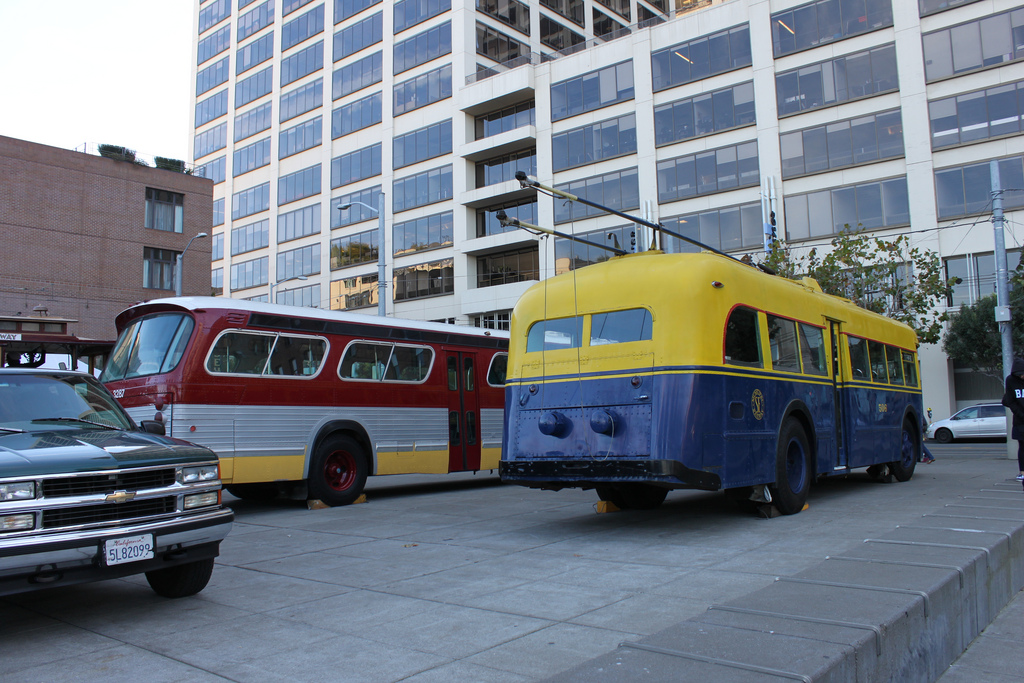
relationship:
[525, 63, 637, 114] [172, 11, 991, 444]
window on building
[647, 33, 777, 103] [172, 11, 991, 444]
window on building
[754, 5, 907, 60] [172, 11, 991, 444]
window on building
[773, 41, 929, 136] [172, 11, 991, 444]
window on building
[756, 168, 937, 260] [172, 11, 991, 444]
window on building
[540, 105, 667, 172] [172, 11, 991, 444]
window on building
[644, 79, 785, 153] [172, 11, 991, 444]
window on building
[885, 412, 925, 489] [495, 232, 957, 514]
tire on bus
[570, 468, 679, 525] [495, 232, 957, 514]
tire on bus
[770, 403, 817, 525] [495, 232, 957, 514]
tire on bus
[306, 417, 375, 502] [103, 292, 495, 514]
tire on bus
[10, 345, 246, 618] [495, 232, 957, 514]
suv in front of bus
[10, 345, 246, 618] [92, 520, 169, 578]
suv with license plate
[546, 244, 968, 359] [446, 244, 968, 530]
tree in front of bus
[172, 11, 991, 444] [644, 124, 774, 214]
building with window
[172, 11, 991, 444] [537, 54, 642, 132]
building with window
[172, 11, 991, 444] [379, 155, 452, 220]
building with window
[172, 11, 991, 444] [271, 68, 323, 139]
building with window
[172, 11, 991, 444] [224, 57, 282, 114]
building with window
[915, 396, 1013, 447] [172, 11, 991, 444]
van in front of building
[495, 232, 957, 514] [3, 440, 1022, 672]
bus on top of concrete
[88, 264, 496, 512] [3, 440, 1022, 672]
bus on top of concrete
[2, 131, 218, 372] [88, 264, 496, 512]
building in back of bus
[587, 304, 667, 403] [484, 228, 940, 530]
window on bus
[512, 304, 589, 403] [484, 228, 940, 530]
window on bus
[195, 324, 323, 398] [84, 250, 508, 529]
window on bus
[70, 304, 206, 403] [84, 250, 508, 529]
window on bus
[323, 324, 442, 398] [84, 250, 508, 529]
window on bus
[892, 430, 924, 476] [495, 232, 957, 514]
tire on bus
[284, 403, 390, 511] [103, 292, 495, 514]
tire on bus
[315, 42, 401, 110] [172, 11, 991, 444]
window on building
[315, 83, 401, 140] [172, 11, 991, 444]
window on building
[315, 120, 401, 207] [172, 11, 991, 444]
window on building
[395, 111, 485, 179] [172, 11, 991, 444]
window on building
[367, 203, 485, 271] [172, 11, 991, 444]
window on building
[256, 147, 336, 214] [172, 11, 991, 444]
window on building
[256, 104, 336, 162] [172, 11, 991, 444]
window on building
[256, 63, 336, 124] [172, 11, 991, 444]
window on building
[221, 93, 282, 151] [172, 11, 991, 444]
window on building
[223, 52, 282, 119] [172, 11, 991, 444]
window on building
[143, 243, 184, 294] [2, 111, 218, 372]
window of building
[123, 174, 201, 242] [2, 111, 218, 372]
window of building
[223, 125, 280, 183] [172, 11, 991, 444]
window of building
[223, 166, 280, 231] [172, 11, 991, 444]
window of building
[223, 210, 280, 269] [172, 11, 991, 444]
window of building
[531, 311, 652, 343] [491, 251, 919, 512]
window of bus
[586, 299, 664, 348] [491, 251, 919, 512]
window of bus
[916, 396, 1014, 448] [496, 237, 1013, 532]
van behind bus